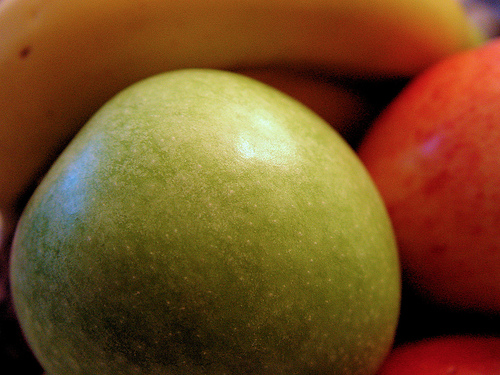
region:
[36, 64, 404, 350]
The fruit is green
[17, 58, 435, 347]
The fruit is an apple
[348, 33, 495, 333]
The fruit is red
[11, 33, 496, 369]
Two different colored apples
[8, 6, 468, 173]
The banana is yellow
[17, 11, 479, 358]
Fruit piled on top of each other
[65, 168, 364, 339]
Apple has yellow specks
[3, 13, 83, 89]
Banana has a brown spot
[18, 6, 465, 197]
Banana on top of apples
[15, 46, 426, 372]
The apple is round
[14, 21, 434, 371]
a green apple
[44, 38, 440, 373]
a fresh green apple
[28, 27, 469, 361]
an uneaten green apple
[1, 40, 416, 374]
an apple that is green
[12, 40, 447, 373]
an apple that is fresh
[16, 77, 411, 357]
an apple that is clean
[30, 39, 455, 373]
an apples that is not eaten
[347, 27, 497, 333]
a red apple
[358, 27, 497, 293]
an apple that is red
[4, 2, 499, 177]
a yellow fresh banana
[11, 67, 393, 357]
green fruit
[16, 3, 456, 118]
yellow banana on the top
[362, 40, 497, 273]
red apple to the right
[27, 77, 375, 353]
green apple in the middle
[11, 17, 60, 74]
black spot on the banana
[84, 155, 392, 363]
many white spots on the green apple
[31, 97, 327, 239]
light reflection on the shiny apple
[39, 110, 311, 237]
overhead light reflecting on the apple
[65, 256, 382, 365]
dark underside section of the apple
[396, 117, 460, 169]
light reflection on the red apple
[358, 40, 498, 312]
red apple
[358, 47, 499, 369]
two red apples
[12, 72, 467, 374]
green apple by two red apples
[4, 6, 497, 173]
yellow bananas behind the apples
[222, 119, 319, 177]
light shining on the apple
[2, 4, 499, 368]
a bunch of fruit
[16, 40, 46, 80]
small brown spot on the banan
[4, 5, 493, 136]
long yellow banana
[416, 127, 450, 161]
light shining on the red apple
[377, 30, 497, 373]
apple on top of another apple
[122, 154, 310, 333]
this is an apple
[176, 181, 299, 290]
the apple is green in color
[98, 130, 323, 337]
the apple is big in size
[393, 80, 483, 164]
the apple is red in color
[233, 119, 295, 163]
the apple is shiny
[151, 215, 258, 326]
the apple is fresh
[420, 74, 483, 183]
the color is bright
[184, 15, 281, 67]
this is a banana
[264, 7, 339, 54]
the banana is yellow in color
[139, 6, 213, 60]
the banana is big in size